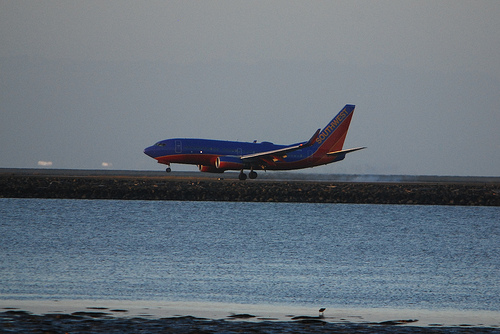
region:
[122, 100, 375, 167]
This is an airplane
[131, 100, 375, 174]
Airplane owned by Southwest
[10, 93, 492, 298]
Airplane over the water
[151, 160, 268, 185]
Airplane's wheels are out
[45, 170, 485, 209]
Long rock wall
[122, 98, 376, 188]
Left side of the plane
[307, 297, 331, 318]
Small bird on the shore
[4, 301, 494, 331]
The shore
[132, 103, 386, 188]
The plane is flying very low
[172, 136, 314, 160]
Windows along the side of the plane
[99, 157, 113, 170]
White object in the background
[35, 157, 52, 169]
White object in the background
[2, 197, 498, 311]
Large body of water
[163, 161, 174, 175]
Front wheel of the plane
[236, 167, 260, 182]
Side wheel of the plane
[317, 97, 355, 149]
Red and blue plane tail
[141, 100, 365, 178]
Red and blue plane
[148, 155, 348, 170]
Red under belly of plane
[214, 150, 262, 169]
Red and blue engine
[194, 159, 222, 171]
Red and blue engine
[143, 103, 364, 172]
red and blue plane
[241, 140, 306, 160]
wing on side of plane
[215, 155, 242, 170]
booster jet on plane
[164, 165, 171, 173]
black tire on plane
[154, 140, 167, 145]
cockpit window on plane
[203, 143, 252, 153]
windows on side of plane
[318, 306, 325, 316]
bird standing on sand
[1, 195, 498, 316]
water next to runway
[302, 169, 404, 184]
smoke from landing plane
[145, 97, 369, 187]
Southwest Airlines plane sitting on a runway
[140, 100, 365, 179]
plane is blue and red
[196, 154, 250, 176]
plane has two engines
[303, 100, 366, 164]
tail of plane says Southwest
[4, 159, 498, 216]
runway next to a body of water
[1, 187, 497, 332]
large body of water next to an airport runway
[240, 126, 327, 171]
wing of an airplane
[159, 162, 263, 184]
wheels of an airplane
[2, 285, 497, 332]
beach by the airport runway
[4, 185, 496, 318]
water is calm and blue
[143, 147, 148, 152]
The nose of the plane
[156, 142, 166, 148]
The plane's cockpit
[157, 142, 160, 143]
The window of the cockpit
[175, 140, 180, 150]
The door of the plane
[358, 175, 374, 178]
Smoke from the plane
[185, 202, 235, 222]
Water next to the runway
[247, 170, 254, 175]
Wheel on the ground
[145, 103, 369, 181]
the airplane is red and blue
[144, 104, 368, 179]
the airplane has black wheels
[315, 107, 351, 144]
the word SOUTHWEST is yellow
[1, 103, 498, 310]
the airplane is near the water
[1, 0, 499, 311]
the sky above the water